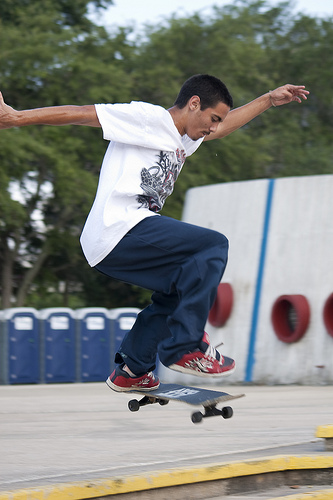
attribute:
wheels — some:
[125, 395, 240, 424]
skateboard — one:
[116, 370, 245, 420]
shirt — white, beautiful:
[95, 98, 179, 267]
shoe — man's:
[104, 366, 159, 395]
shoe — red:
[137, 365, 307, 391]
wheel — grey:
[193, 404, 226, 425]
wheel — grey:
[110, 389, 160, 442]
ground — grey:
[29, 407, 104, 480]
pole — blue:
[179, 167, 315, 251]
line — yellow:
[158, 432, 226, 485]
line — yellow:
[222, 450, 260, 474]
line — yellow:
[221, 465, 255, 479]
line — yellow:
[150, 420, 253, 498]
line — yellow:
[139, 450, 211, 497]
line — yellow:
[149, 464, 193, 496]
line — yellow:
[166, 454, 224, 490]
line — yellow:
[126, 456, 241, 495]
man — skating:
[90, 84, 216, 248]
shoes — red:
[161, 345, 273, 436]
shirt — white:
[42, 94, 157, 184]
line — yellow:
[126, 416, 253, 476]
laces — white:
[191, 319, 250, 377]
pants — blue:
[103, 232, 217, 310]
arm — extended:
[229, 62, 279, 143]